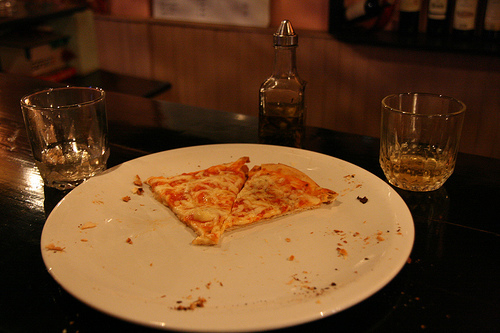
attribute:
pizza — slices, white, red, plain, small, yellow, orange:
[144, 153, 341, 247]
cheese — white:
[170, 181, 237, 222]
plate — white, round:
[31, 138, 420, 329]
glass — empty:
[359, 82, 475, 197]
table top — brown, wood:
[4, 114, 499, 325]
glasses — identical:
[20, 72, 465, 201]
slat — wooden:
[93, 8, 275, 44]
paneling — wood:
[173, 25, 258, 109]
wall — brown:
[320, 54, 372, 132]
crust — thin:
[147, 153, 252, 182]